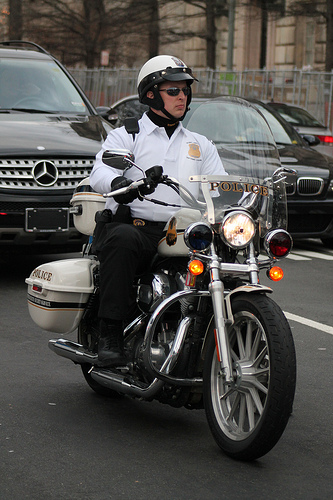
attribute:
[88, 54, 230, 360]
police officer — riding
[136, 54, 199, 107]
helmet — black, white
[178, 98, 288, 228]
windshield — clear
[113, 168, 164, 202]
glove — black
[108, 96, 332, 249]
car — black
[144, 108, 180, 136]
turtleneck — black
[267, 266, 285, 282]
light — yellow, orange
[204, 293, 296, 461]
wheel — silver, black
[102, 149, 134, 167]
rearview mirror — rear-view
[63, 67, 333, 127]
fence — tall, chainlink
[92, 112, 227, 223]
shirt — white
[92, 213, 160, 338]
pants — black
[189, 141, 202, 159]
shield — embroidered, yellow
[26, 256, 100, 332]
tank — white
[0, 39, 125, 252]
suv — black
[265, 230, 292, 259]
emergency light — red